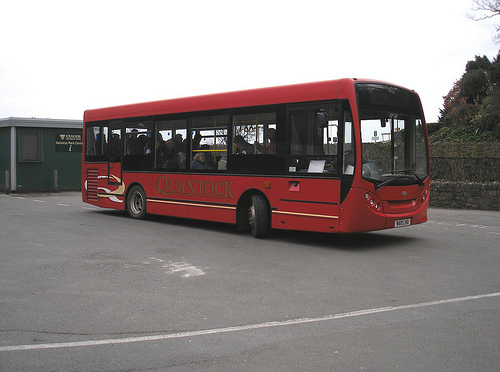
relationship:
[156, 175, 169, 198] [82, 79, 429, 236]
q on bus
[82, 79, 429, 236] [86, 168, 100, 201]
bus has vent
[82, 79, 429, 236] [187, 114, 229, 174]
bus has window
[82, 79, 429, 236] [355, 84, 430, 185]
bus has windshield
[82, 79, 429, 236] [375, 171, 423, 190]
bus has wipers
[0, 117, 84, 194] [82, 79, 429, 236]
building behind bus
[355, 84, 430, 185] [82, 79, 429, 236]
window in front of bus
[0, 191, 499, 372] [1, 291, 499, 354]
pavement has line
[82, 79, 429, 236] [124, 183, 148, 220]
bus has wheel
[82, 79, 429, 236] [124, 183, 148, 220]
bus has tire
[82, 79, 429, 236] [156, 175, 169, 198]
bus has q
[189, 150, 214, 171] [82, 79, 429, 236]
passenger on bus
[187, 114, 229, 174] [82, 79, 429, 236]
window along bus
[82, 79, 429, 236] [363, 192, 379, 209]
bus has headlights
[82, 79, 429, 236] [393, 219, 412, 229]
bus has tag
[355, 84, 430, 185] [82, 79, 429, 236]
windshield in front of bus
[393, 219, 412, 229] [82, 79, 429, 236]
tag on bus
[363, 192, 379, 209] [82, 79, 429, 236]
headlights on bus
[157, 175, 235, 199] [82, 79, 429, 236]
letters on bus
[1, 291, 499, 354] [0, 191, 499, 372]
line on pavement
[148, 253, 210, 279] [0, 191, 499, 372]
spill on pavement